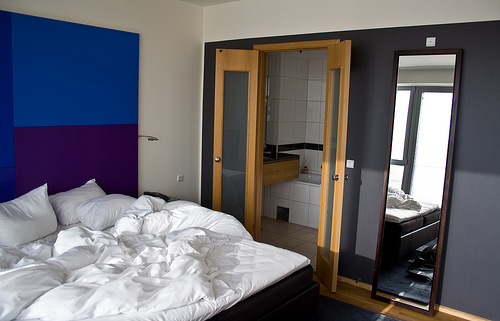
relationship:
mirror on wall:
[371, 48, 459, 316] [338, 22, 499, 320]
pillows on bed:
[0, 177, 137, 256] [1, 179, 318, 320]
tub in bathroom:
[264, 175, 321, 229] [262, 50, 328, 270]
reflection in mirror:
[378, 66, 454, 294] [371, 48, 459, 316]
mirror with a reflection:
[371, 48, 459, 316] [378, 66, 454, 294]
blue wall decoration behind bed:
[1, 10, 140, 126] [1, 179, 318, 320]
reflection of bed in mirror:
[385, 187, 440, 256] [371, 48, 459, 316]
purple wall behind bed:
[16, 127, 139, 195] [1, 179, 318, 320]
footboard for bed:
[214, 266, 395, 319] [1, 179, 318, 320]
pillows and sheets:
[0, 177, 137, 256] [0, 195, 253, 320]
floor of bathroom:
[261, 217, 317, 271] [262, 50, 328, 270]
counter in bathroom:
[263, 153, 301, 183] [262, 50, 328, 270]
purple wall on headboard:
[16, 127, 139, 195] [2, 12, 137, 199]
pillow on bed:
[2, 183, 58, 245] [1, 179, 318, 320]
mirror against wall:
[371, 48, 459, 316] [338, 22, 499, 320]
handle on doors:
[334, 173, 349, 182] [210, 36, 354, 293]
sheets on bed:
[0, 195, 253, 320] [1, 179, 318, 320]